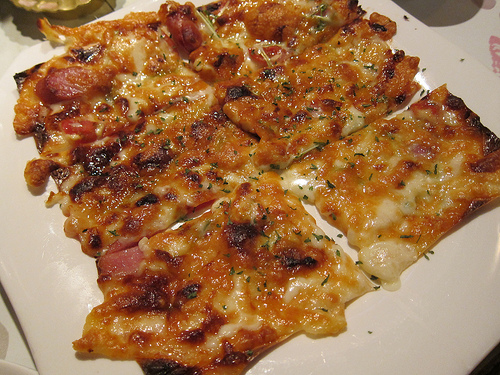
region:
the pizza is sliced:
[23, 67, 436, 372]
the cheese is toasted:
[21, 37, 443, 366]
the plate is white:
[18, 33, 453, 363]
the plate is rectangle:
[11, 10, 497, 374]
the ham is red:
[85, 243, 166, 283]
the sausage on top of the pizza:
[25, 52, 102, 99]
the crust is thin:
[13, 23, 390, 351]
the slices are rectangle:
[26, 22, 397, 373]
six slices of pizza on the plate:
[22, 11, 475, 368]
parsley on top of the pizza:
[11, 8, 498, 369]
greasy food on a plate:
[85, 24, 387, 355]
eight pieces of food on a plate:
[46, 9, 498, 333]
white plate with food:
[15, 1, 479, 360]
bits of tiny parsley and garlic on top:
[54, 0, 462, 355]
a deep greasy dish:
[64, 25, 463, 361]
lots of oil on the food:
[52, 32, 422, 327]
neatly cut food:
[289, 50, 476, 293]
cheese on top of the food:
[16, 41, 393, 373]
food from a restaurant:
[6, 2, 461, 368]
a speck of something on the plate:
[264, 237, 455, 359]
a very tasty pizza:
[34, 31, 499, 349]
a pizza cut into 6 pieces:
[37, 23, 495, 362]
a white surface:
[346, 279, 481, 341]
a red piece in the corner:
[450, 31, 497, 65]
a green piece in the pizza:
[190, 3, 240, 50]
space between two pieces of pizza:
[297, 196, 360, 258]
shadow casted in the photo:
[415, 0, 469, 55]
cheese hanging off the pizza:
[15, 83, 70, 231]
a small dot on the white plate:
[358, 323, 388, 334]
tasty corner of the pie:
[379, 46, 451, 242]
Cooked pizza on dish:
[11, 1, 498, 373]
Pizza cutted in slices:
[11, 0, 489, 374]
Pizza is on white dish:
[2, 7, 489, 374]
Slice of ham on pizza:
[35, 55, 96, 110]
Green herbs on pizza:
[174, 67, 435, 308]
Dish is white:
[1, 2, 498, 373]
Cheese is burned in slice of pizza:
[54, 132, 174, 210]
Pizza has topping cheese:
[21, 7, 488, 352]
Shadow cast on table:
[4, 2, 122, 47]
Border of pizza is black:
[437, 88, 498, 150]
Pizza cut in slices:
[10, 0, 499, 370]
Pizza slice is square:
[72, 174, 368, 373]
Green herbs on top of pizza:
[189, 102, 375, 291]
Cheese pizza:
[18, 1, 499, 372]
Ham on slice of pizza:
[87, 236, 152, 283]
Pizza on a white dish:
[3, 0, 498, 374]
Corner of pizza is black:
[8, 52, 52, 93]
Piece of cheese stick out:
[68, 279, 178, 366]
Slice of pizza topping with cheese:
[281, 83, 499, 292]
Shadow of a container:
[10, 8, 115, 46]